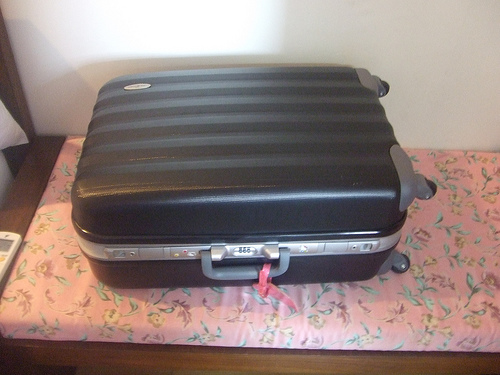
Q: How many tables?
A: One.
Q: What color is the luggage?
A: Black.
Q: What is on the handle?
A: Tag.